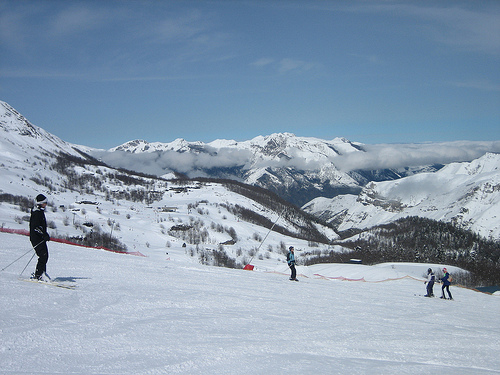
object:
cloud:
[0, 0, 499, 152]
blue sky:
[0, 1, 499, 151]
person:
[26, 194, 51, 280]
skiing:
[0, 194, 79, 291]